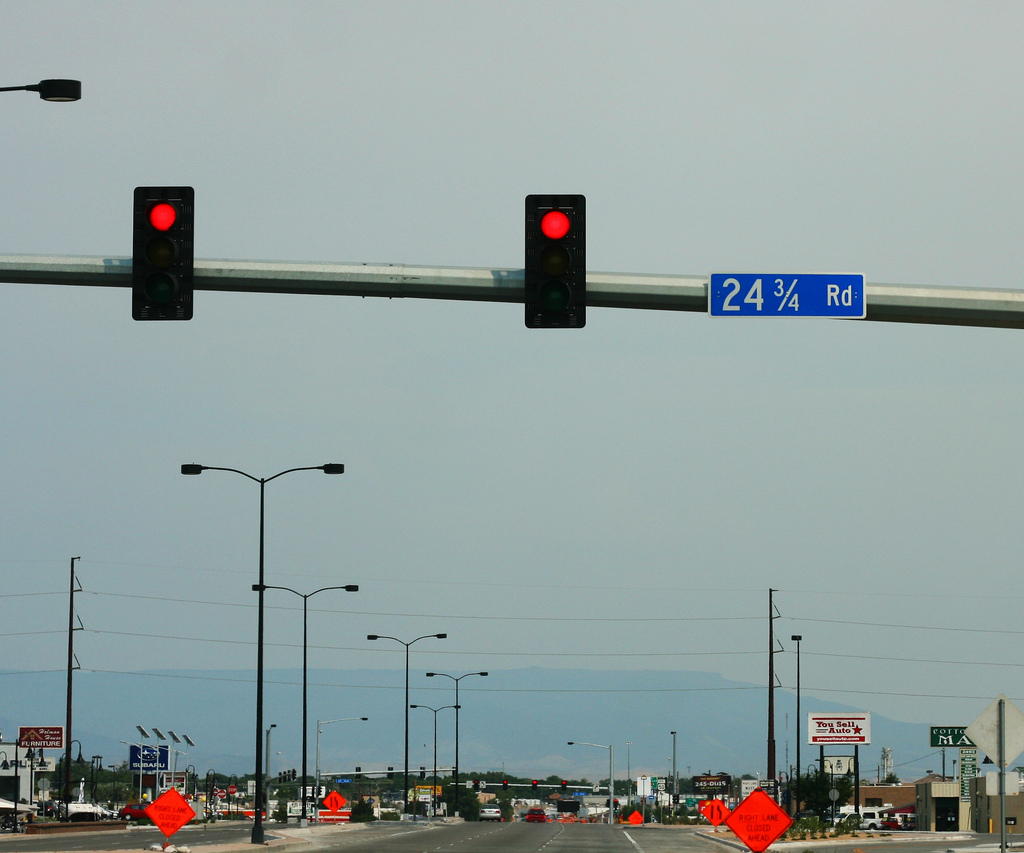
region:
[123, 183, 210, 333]
black traffic signal in air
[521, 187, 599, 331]
black traffic signal in air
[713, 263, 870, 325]
blue street sign on pole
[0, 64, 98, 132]
black street light in air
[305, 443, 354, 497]
black street light in air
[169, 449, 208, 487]
black street light in air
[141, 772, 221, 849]
orange and black road sign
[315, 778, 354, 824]
orange and black road sign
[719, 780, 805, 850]
orange and black road sign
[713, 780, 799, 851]
Orange and black traffic sign on the road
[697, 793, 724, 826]
Orange and black traffic sign on the road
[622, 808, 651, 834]
Orange and black traffic sign on the road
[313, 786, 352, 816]
Orange and black traffic sign on the road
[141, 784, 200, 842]
Orange and black traffic sign on the road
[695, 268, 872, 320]
traffic sign is blue and white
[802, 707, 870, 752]
billboard is red and white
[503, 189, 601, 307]
traffic light is red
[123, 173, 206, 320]
traffic light is red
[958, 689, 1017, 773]
traffic sign on the pole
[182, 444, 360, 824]
A tall street light.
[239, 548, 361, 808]
A tall street light.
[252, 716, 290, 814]
A tall street light.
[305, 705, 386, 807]
A tall street light.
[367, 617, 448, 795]
A tall street light.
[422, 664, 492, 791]
A tall street light.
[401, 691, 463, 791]
A tall street light.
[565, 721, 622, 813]
A tall street light.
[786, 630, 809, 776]
A tall street light.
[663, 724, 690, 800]
A tall street light.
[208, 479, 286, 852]
a street light on the side of road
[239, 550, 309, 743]
a street light on the side of road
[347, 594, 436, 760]
a street light on the side of road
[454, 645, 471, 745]
a street light on the side of road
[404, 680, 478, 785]
a street light on the side of road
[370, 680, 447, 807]
a street light on the side of road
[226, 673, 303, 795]
a street light on the side of road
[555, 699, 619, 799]
a street light on the side of road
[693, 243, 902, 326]
blue and white street sign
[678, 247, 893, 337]
blue and white street sign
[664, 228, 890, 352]
blue and white street sign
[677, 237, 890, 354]
blue and white street sign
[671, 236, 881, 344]
blue and white street sign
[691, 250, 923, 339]
blue and white street sign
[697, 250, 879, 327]
blue and white street sign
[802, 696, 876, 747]
A white and red store sign.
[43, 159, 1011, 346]
Two traffic lights on a metal post.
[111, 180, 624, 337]
The traffic lights are red.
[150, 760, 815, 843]
Construction signs on both sides of the road.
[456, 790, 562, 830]
Cars at the far intersection.